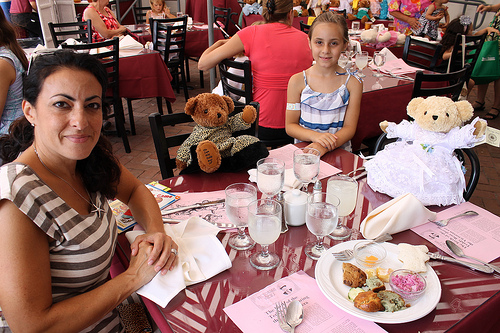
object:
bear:
[176, 93, 270, 174]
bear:
[364, 96, 487, 206]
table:
[106, 141, 498, 333]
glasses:
[246, 199, 283, 271]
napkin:
[360, 191, 437, 239]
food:
[342, 261, 424, 313]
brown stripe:
[27, 185, 61, 222]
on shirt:
[0, 162, 126, 333]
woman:
[0, 51, 178, 332]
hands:
[128, 233, 179, 281]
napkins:
[124, 216, 233, 308]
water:
[307, 202, 338, 235]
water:
[249, 207, 282, 244]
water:
[294, 153, 319, 181]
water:
[258, 163, 285, 194]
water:
[226, 192, 257, 224]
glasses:
[225, 183, 258, 251]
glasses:
[305, 192, 341, 260]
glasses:
[292, 147, 320, 192]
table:
[20, 47, 159, 61]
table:
[122, 20, 221, 38]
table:
[336, 57, 446, 94]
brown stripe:
[8, 162, 17, 188]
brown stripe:
[11, 179, 45, 208]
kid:
[284, 13, 364, 158]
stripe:
[48, 227, 116, 284]